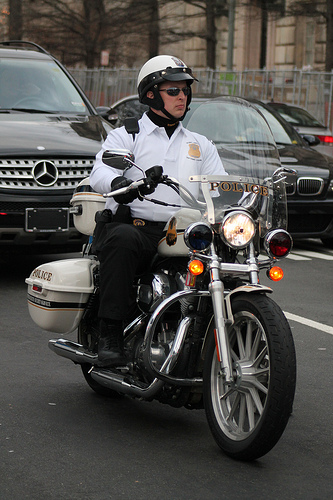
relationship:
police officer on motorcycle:
[88, 54, 230, 360] [25, 100, 324, 460]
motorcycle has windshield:
[25, 100, 324, 460] [178, 98, 288, 228]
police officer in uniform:
[88, 54, 230, 360] [96, 113, 231, 330]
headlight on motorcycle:
[219, 210, 257, 248] [25, 100, 324, 460]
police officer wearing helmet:
[88, 54, 230, 360] [136, 54, 199, 107]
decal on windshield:
[206, 182, 272, 196] [178, 98, 288, 228]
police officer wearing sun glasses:
[88, 54, 230, 360] [156, 86, 192, 97]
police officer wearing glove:
[88, 54, 230, 360] [113, 168, 164, 202]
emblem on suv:
[32, 158, 59, 185] [0, 39, 125, 252]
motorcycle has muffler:
[25, 100, 324, 460] [44, 338, 104, 371]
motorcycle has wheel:
[25, 100, 324, 460] [204, 293, 296, 461]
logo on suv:
[32, 158, 59, 185] [0, 39, 125, 252]